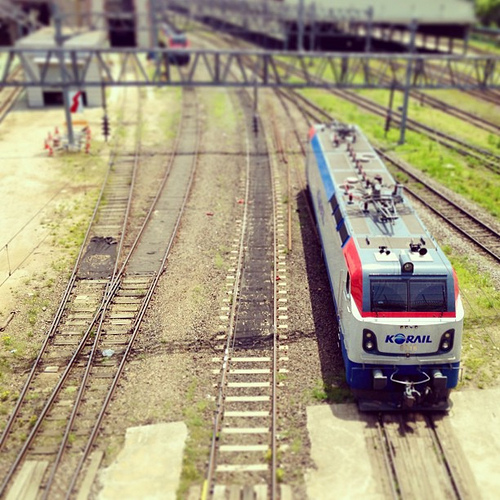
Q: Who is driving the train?
A: The conductor.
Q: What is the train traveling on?
A: Tracks.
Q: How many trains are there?
A: Two.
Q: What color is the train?
A: Red, blue, and gray.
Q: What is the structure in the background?
A: A storage area.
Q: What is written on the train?
A: Korail.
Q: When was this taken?
A: During the day.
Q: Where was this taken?
A: At a train yard.